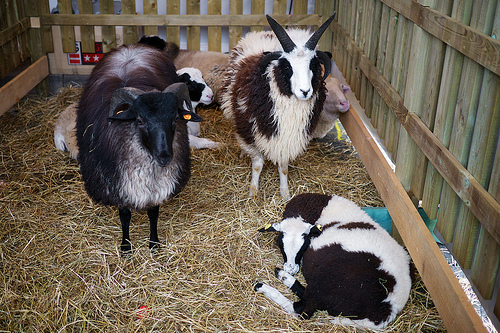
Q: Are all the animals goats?
A: No, there are both sheep and goats.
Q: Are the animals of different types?
A: Yes, they are sheep and goats.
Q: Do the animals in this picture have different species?
A: Yes, they are sheep and goats.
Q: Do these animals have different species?
A: Yes, they are sheep and goats.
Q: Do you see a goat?
A: Yes, there is a goat.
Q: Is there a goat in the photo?
A: Yes, there is a goat.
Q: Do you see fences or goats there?
A: Yes, there is a goat.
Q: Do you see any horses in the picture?
A: No, there are no horses.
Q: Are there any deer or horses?
A: No, there are no horses or deer.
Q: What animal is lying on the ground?
A: The goat is lying on the ground.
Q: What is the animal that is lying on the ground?
A: The animal is a goat.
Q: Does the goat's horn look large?
A: Yes, the horn is large.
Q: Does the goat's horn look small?
A: No, the horn is large.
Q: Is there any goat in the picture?
A: Yes, there is a goat.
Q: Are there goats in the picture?
A: Yes, there is a goat.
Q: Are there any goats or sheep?
A: Yes, there is a goat.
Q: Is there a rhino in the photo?
A: No, there are no rhinos.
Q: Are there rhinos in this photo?
A: No, there are no rhinos.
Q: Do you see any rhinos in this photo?
A: No, there are no rhinos.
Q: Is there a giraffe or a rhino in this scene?
A: No, there are no rhinos or giraffes.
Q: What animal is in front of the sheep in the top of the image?
A: The goat is in front of the sheep.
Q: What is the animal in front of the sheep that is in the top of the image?
A: The animal is a goat.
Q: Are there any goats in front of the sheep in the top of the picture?
A: Yes, there is a goat in front of the sheep.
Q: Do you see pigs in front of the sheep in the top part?
A: No, there is a goat in front of the sheep.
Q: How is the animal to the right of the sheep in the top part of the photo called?
A: The animal is a goat.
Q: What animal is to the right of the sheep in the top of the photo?
A: The animal is a goat.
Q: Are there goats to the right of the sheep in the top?
A: Yes, there is a goat to the right of the sheep.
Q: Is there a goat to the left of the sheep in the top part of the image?
A: No, the goat is to the right of the sheep.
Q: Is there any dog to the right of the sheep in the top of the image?
A: No, there is a goat to the right of the sheep.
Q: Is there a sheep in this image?
A: Yes, there is a sheep.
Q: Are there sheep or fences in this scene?
A: Yes, there is a sheep.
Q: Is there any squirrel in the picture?
A: No, there are no squirrels.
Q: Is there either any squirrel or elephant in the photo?
A: No, there are no squirrels or elephants.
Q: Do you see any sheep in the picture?
A: Yes, there is a sheep.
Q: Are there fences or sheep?
A: Yes, there is a sheep.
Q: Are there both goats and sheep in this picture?
A: Yes, there are both a sheep and goats.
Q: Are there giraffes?
A: No, there are no giraffes.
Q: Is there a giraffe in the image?
A: No, there are no giraffes.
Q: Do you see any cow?
A: No, there are no cows.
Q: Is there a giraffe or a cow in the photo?
A: No, there are no cows or giraffes.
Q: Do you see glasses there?
A: No, there are no glasses.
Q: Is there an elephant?
A: No, there are no elephants.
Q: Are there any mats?
A: No, there are no mats.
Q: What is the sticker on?
A: The sticker is on the wall.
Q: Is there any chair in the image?
A: No, there are no chairs.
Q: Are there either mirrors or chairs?
A: No, there are no chairs or mirrors.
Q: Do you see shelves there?
A: No, there are no shelves.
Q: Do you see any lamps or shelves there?
A: No, there are no shelves or lamps.